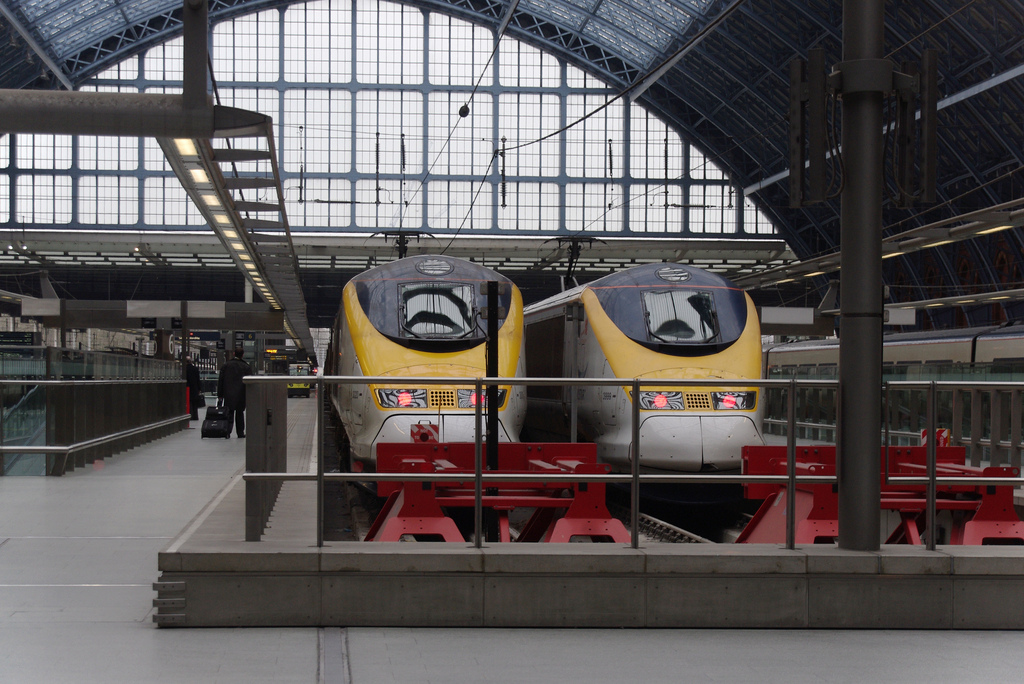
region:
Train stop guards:
[361, 421, 1020, 555]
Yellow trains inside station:
[331, 250, 766, 463]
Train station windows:
[0, 3, 784, 236]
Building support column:
[841, 0, 886, 555]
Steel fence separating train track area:
[240, 360, 1021, 542]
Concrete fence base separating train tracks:
[152, 469, 1010, 628]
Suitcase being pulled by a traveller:
[198, 404, 236, 440]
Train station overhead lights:
[2, 88, 317, 349]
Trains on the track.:
[319, 173, 920, 651]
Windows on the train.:
[227, 191, 807, 626]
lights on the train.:
[353, 214, 559, 553]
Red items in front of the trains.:
[329, 248, 979, 682]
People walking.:
[135, 233, 285, 512]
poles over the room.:
[328, 20, 918, 256]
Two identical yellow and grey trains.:
[327, 252, 768, 505]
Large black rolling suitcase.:
[200, 405, 233, 440]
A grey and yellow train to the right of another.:
[523, 264, 770, 505]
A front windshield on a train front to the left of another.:
[396, 280, 476, 337]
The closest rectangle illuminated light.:
[172, 134, 196, 160]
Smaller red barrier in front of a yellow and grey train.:
[365, 438, 635, 540]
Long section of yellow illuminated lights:
[171, 137, 311, 365]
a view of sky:
[294, 53, 481, 165]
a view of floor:
[6, 454, 118, 554]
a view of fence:
[246, 435, 544, 617]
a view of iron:
[385, 372, 567, 506]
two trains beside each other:
[316, 259, 702, 460]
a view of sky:
[252, 51, 506, 222]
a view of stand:
[381, 432, 601, 516]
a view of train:
[322, 252, 667, 569]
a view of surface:
[66, 489, 181, 639]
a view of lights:
[350, 351, 434, 447]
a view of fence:
[274, 51, 544, 197]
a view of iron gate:
[303, 351, 629, 545]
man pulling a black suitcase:
[192, 386, 241, 438]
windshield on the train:
[389, 259, 489, 359]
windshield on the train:
[641, 285, 737, 350]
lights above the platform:
[173, 138, 298, 319]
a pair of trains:
[312, 215, 777, 522]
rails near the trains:
[203, 361, 1019, 573]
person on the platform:
[181, 334, 261, 462]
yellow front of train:
[322, 279, 557, 438]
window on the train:
[385, 268, 513, 361]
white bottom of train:
[603, 402, 765, 483]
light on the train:
[622, 376, 765, 421]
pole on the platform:
[813, 37, 918, 550]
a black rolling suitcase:
[186, 386, 245, 451]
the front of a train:
[335, 254, 522, 483]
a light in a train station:
[163, 148, 266, 278]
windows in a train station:
[166, 59, 639, 230]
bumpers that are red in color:
[364, 448, 618, 553]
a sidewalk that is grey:
[115, 428, 240, 528]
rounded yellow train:
[560, 239, 761, 477]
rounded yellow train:
[346, 220, 521, 458]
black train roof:
[359, 237, 506, 355]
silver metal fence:
[225, 351, 993, 571]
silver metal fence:
[13, 369, 201, 474]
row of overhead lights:
[160, 132, 290, 361]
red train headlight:
[396, 385, 420, 418]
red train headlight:
[460, 379, 496, 415]